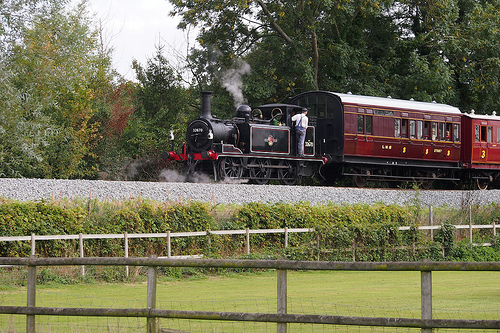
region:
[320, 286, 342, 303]
Small patch of the green grass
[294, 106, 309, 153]
Train conductor outside of the train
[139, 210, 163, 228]
Small patch of a green shrub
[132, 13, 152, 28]
A white overcast sky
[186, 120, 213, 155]
Black front of the train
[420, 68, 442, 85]
Green leaves off of a tree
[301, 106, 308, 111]
Gray hat of a train conductor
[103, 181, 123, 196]
Small patch of gray rocks on train tracks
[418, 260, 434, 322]
Small part of a fence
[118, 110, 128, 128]
Red leaves on the tree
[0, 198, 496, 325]
a wooden fence with wooden posts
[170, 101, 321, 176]
a black train engine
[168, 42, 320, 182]
smoke coming from a black train engine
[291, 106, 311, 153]
a man looking backward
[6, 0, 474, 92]
a white colored sky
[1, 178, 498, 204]
gray colored gravels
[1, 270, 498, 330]
flat pasture land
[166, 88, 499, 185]
a black engine and red cars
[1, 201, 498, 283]
a weed covered bank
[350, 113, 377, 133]
two dark windows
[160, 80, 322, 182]
an old fashioned steam engine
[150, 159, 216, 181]
cattle guard on the engine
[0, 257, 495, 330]
wooden fence below the tracks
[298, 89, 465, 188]
dark red passenger car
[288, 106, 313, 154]
the engineer of the train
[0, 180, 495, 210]
gravel on the railroad bed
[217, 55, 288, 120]
smoke from the heat source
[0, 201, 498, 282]
foliage along the fence line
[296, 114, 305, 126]
the straps at the top of the overalls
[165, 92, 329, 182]
a black train engine with red on the front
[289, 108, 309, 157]
a man wearing blue jean overalls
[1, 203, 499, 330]
a wooden fence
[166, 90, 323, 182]
a black train engine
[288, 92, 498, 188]
two red train cars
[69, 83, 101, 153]
yellow leaves on a tree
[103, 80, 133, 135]
red leaves on a tree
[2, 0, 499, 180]
trees beside the traing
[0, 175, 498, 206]
gray colored gravel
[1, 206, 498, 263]
weeds growing on the small bank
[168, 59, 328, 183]
smoke is coming from the engine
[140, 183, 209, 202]
gravel next to the train track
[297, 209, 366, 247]
plants growing on the fence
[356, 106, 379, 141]
windows on the train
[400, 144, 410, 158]
yellow number on the side of the train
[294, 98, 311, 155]
a man on the side on the train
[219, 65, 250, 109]
steam coming out of the train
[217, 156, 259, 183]
wheels on the train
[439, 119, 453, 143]
people looking out the windows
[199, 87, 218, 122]
smoke stack on the train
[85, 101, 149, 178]
trees growing beside the train tracks